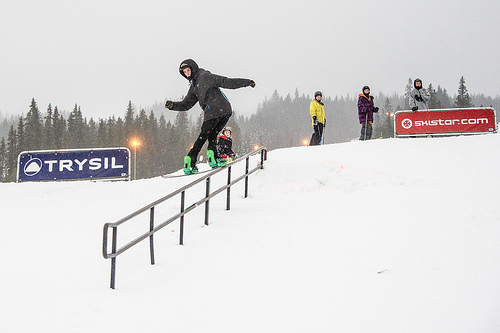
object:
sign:
[15, 147, 132, 185]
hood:
[164, 58, 255, 168]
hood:
[308, 92, 327, 146]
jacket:
[169, 69, 251, 123]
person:
[356, 85, 378, 141]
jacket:
[409, 87, 432, 109]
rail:
[101, 146, 266, 291]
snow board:
[161, 166, 221, 179]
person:
[308, 91, 327, 147]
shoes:
[183, 155, 199, 175]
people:
[308, 78, 432, 146]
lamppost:
[130, 138, 141, 183]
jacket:
[309, 100, 327, 125]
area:
[0, 106, 499, 332]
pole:
[132, 146, 136, 180]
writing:
[44, 156, 124, 172]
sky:
[2, 2, 498, 102]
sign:
[393, 106, 497, 138]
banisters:
[102, 145, 268, 289]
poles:
[363, 111, 368, 140]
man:
[309, 91, 327, 147]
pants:
[188, 114, 232, 165]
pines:
[0, 98, 66, 184]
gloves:
[249, 80, 256, 89]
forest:
[0, 75, 499, 184]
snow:
[181, 259, 484, 320]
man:
[164, 59, 255, 175]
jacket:
[357, 93, 376, 124]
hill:
[0, 130, 499, 332]